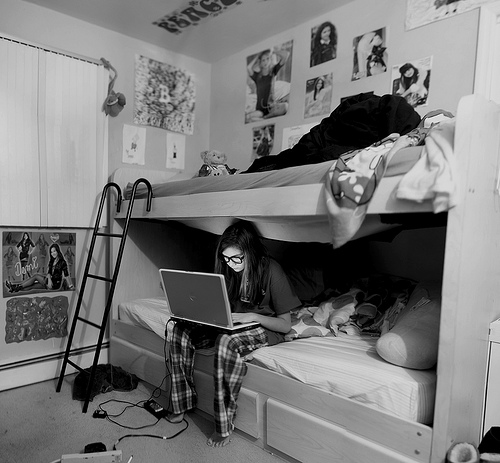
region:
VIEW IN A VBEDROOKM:
[130, 104, 345, 341]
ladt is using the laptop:
[150, 202, 330, 429]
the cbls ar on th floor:
[83, 389, 165, 461]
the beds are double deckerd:
[272, 153, 433, 431]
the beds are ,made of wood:
[236, 384, 373, 461]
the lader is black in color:
[46, 203, 126, 395]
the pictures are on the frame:
[8, 220, 115, 369]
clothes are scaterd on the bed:
[230, 77, 377, 152]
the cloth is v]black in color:
[310, 102, 428, 154]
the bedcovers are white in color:
[322, 338, 422, 437]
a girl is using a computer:
[154, 226, 291, 448]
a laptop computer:
[158, 268, 258, 331]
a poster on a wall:
[243, 41, 293, 127]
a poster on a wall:
[390, 58, 432, 110]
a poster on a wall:
[350, 27, 387, 78]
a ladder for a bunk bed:
[50, 173, 151, 420]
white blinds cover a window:
[0, 34, 115, 230]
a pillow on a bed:
[378, 279, 445, 376]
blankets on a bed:
[289, 270, 412, 340]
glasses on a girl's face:
[222, 252, 246, 265]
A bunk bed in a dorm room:
[100, 85, 498, 460]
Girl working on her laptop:
[147, 215, 303, 357]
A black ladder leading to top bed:
[45, 165, 160, 415]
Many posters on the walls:
[110, 0, 485, 175]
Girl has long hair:
[205, 212, 271, 307]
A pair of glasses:
[212, 246, 252, 266]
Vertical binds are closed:
[0, 25, 112, 235]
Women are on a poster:
[0, 226, 77, 296]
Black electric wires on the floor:
[87, 381, 188, 451]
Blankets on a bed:
[233, 82, 458, 253]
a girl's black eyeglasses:
[220, 250, 244, 264]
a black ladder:
[53, 178, 155, 415]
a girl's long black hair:
[213, 216, 269, 308]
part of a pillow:
[368, 298, 445, 373]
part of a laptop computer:
[153, 263, 256, 333]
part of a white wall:
[8, 9, 112, 49]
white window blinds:
[3, 35, 112, 232]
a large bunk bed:
[112, 95, 499, 461]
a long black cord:
[106, 417, 191, 459]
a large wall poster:
[242, 37, 296, 121]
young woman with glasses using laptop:
[157, 219, 296, 446]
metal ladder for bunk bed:
[55, 177, 155, 413]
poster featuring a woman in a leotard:
[239, 37, 291, 125]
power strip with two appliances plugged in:
[48, 444, 124, 461]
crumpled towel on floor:
[71, 362, 139, 402]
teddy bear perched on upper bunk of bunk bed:
[198, 149, 236, 177]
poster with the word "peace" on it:
[151, 1, 241, 41]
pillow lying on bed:
[372, 281, 444, 371]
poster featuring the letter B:
[133, 52, 198, 136]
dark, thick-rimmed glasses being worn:
[220, 250, 249, 264]